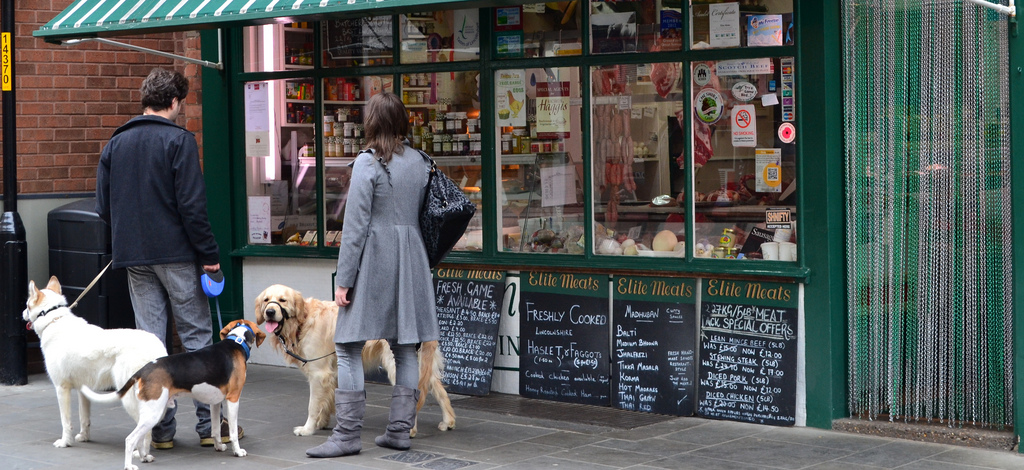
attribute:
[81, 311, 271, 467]
dog — brown, black, white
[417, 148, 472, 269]
purse — large, black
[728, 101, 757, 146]
sign — red, white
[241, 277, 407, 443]
brown dog — light brown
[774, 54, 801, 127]
window sticker — credit card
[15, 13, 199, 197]
wall — brick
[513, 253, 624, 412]
sign — black, green